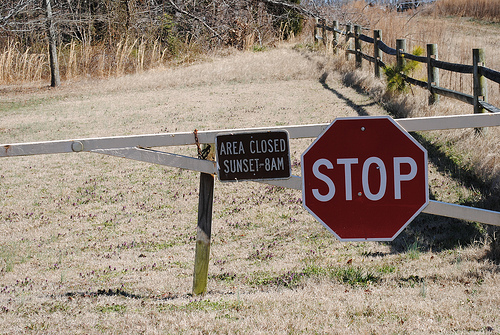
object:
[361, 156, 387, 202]
words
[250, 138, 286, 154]
closed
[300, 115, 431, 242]
stop sign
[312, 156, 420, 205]
stop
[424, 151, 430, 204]
sides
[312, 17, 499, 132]
fence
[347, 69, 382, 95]
grass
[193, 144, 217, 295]
post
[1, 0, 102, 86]
pine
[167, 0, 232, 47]
tree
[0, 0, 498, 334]
park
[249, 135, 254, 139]
screw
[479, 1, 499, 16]
bushes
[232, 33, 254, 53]
stump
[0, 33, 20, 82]
brush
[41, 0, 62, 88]
trunk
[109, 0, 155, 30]
trees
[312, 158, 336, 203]
s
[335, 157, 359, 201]
t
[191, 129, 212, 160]
chain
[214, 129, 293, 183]
sign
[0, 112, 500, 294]
railings